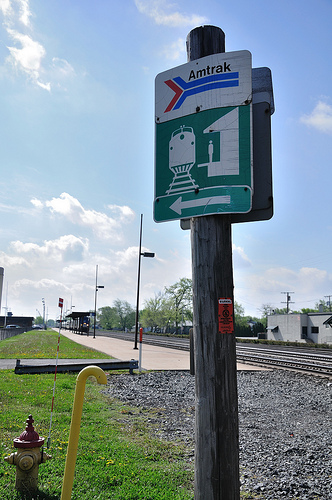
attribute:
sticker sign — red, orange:
[214, 297, 235, 337]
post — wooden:
[186, 29, 231, 499]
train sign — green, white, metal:
[150, 59, 277, 229]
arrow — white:
[164, 196, 232, 212]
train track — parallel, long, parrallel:
[72, 323, 332, 381]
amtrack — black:
[189, 58, 235, 79]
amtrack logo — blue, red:
[161, 73, 240, 110]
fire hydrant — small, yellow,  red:
[7, 413, 51, 495]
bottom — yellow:
[4, 449, 57, 493]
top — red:
[13, 416, 45, 448]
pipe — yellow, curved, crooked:
[59, 362, 107, 500]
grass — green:
[11, 325, 76, 357]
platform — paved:
[84, 336, 258, 371]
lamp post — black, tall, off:
[130, 207, 155, 351]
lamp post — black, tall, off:
[91, 266, 107, 341]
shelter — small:
[69, 309, 96, 336]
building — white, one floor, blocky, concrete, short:
[268, 313, 331, 343]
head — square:
[137, 248, 155, 261]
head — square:
[99, 283, 104, 291]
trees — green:
[107, 285, 258, 336]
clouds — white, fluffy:
[22, 203, 129, 294]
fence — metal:
[0, 326, 38, 342]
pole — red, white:
[46, 295, 63, 456]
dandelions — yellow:
[95, 457, 119, 477]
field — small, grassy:
[6, 380, 144, 494]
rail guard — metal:
[22, 364, 143, 372]